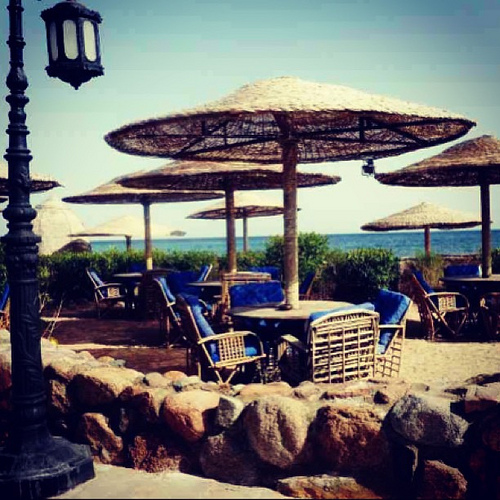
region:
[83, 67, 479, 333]
large umbrella made of wicker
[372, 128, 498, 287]
large umbrella made of wicker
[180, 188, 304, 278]
large umbrella made of wicker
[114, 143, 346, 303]
large umbrella made of wicker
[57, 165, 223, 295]
large umbrella made of wicker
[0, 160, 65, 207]
large umbrella made of wicker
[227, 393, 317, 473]
large rock as part of a wall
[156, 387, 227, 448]
large rock as part of a wall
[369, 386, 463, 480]
large rock as part of a wall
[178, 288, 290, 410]
decrorative chairs with blue cushion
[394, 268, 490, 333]
decrorative chairs with blue cushion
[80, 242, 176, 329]
decrorative chairs with blue cushion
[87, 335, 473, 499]
decorative rocks used in wall for patio area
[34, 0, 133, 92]
black decorative light with white panes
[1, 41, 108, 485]
black decorative pole for lights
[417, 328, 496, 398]
sand in patio area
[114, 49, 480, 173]
hut type umbrella for outside patio area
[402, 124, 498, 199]
hut type umbrella for outside patio area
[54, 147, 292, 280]
hut type umbrella for outside patio area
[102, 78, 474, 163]
a wicker sunshade umbrella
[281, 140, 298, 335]
the pole for the wicker sun umbrella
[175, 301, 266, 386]
a wicker chair with blue cushions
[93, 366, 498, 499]
a rock wall along the table and chairs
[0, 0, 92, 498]
a lamp and pole outside the rock wall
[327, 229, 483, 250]
blue ocean in the distance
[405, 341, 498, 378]
beach sand in the cabana area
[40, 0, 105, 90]
a hanging lamp on the pole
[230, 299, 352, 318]
a round table under the wicker umbrella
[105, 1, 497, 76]
clear blue sky over the beach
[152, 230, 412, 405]
brown chairs under umbrella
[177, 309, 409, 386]
chairs are brown and wooden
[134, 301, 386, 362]
blue cushions on chairs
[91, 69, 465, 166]
wooden umbrella over tables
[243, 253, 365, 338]
tables are brown and round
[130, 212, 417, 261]
water off in distance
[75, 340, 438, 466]
rock wall in front of tables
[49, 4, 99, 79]
white lamp overhangs rocks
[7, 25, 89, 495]
black decorative post holds lamp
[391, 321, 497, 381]
ground is light brown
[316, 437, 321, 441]
edge of a rock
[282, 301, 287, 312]
edge of a table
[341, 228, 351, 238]
part of the sea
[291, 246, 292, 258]
part of a pole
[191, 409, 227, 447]
edge of a wall